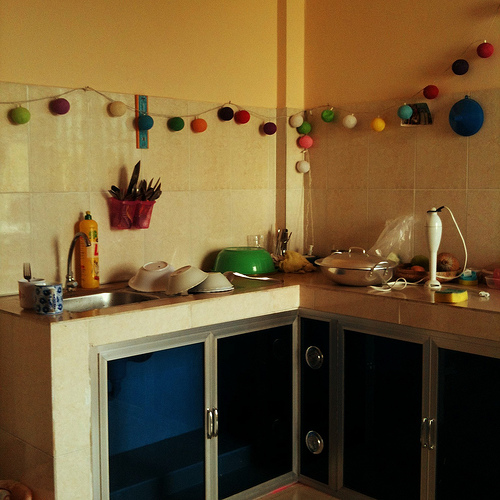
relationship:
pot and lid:
[314, 246, 397, 285] [315, 246, 398, 269]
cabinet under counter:
[96, 308, 300, 500] [7, 255, 319, 333]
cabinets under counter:
[294, 321, 499, 498] [287, 259, 497, 344]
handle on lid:
[346, 247, 366, 254] [313, 247, 395, 268]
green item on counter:
[211, 247, 277, 274] [227, 274, 358, 316]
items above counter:
[20, 41, 484, 131] [13, 283, 496, 483]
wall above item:
[1, 2, 303, 107] [4, 80, 312, 174]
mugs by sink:
[18, 274, 63, 315] [52, 231, 159, 308]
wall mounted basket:
[209, 155, 263, 216] [107, 201, 156, 230]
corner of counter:
[25, 305, 70, 499] [2, 250, 303, 332]